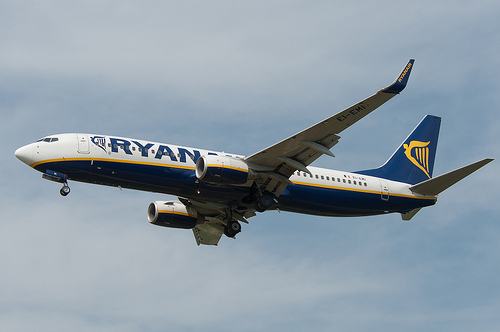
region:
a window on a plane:
[112, 140, 117, 148]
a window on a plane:
[128, 144, 138, 155]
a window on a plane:
[148, 144, 165, 162]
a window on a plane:
[312, 169, 326, 184]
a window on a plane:
[363, 178, 373, 192]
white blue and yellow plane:
[44, 58, 492, 245]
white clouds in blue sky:
[302, 275, 339, 303]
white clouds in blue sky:
[50, 249, 112, 283]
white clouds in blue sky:
[198, 295, 260, 329]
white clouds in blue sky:
[68, 12, 122, 49]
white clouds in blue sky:
[161, 39, 193, 66]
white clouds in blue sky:
[221, 31, 301, 83]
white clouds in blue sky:
[318, 13, 378, 48]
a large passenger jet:
[14, 58, 493, 244]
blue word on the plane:
[108, 133, 203, 170]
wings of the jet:
[191, 56, 413, 245]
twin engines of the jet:
[147, 152, 249, 229]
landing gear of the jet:
[60, 173, 70, 196]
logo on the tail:
[402, 139, 433, 176]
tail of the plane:
[353, 113, 493, 219]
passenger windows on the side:
[291, 170, 370, 186]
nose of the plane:
[13, 138, 39, 168]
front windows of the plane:
[37, 137, 60, 143]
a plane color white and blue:
[11, 48, 498, 277]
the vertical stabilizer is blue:
[353, 110, 449, 176]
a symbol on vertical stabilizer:
[377, 110, 448, 180]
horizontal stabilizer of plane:
[390, 156, 497, 225]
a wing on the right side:
[234, 50, 424, 178]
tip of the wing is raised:
[356, 48, 427, 104]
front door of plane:
[72, 126, 94, 159]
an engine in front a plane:
[187, 145, 262, 187]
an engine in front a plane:
[138, 194, 200, 234]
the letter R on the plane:
[106, 126, 135, 164]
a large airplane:
[12, 58, 494, 247]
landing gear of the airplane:
[60, 179, 70, 195]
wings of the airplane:
[185, 58, 414, 243]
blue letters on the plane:
[109, 136, 199, 162]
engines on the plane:
[146, 154, 249, 229]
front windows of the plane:
[34, 136, 59, 142]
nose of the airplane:
[14, 143, 35, 165]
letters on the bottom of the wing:
[336, 103, 366, 122]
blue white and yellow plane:
[15, 46, 477, 254]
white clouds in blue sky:
[37, 41, 69, 82]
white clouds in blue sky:
[300, 279, 372, 324]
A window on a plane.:
[102, 142, 107, 145]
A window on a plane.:
[107, 140, 112, 147]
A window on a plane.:
[113, 141, 118, 148]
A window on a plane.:
[130, 144, 136, 151]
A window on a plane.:
[138, 146, 143, 153]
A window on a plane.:
[142, 146, 148, 153]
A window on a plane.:
[149, 148, 156, 155]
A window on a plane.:
[166, 150, 171, 155]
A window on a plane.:
[353, 177, 358, 185]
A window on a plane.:
[363, 181, 370, 189]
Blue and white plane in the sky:
[17, 55, 491, 263]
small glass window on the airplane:
[361, 180, 368, 186]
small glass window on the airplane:
[357, 178, 362, 185]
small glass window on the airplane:
[350, 177, 355, 185]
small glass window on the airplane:
[346, 176, 352, 183]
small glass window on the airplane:
[340, 175, 347, 183]